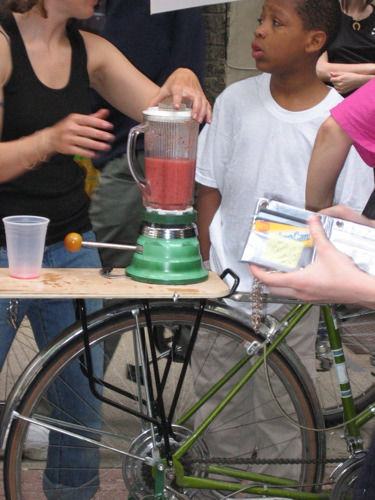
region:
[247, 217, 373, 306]
person's left hand holding papers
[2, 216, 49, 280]
empty plastic cup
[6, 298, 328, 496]
round bike tire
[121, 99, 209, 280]
old fashion green blender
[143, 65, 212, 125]
woman's left hand holding blender lid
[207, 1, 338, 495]
young boy learning from teacher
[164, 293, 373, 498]
lime green bike frame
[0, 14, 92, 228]
woman wearing a black tank top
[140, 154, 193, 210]
red liquid in the blender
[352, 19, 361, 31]
horseshoe charm on the necklace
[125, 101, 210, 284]
A juice blender for making smoothies.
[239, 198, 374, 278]
An open wallet with credit cards.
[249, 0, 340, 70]
A young boys head.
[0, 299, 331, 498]
A bicycle wheel with tire and spokes.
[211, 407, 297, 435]
Silver spoke of the bicycle wheel.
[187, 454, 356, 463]
A black bicycle chain on the bicycle.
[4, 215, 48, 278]
A white plastic cup with a little juice in it.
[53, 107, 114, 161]
A woman's right hand making the drink.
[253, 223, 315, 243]
Part of a plastic card in the customer's wallet.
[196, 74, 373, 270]
A boys neck and white t-shirt.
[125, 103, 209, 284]
a green blender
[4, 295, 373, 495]
a green painted bicycle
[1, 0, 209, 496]
a woman holding blender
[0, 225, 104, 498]
a pair of women's blue jeans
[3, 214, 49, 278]
a clear plastic cup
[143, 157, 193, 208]
pink liquid in blender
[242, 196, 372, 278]
an open wallet with cards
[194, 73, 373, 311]
a child's white t-shirt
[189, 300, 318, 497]
a pair of child's beige pants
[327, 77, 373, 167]
a bright pink shirt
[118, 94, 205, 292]
Green and glass blender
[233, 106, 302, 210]
boy wearing a white shirt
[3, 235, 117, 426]
woman wearing blue jeans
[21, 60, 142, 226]
woman wearing a black shirt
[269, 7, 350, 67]
Boy with short hair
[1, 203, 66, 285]
cup on a platform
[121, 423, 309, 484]
chain on a bike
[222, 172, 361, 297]
person holding a wallet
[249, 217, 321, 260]
metro card in a wallet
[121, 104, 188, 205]
smoothie in a blender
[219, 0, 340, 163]
a young boy wearing a white shirt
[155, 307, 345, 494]
a green bike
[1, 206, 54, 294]
a plastic cup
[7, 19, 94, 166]
a woman wearing a black shirt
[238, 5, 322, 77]
a boy with his head turned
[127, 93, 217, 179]
a white lid on a blender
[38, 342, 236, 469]
spokes on a bike wheel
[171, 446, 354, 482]
a chain on a bike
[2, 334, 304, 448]
a black tire on a bike